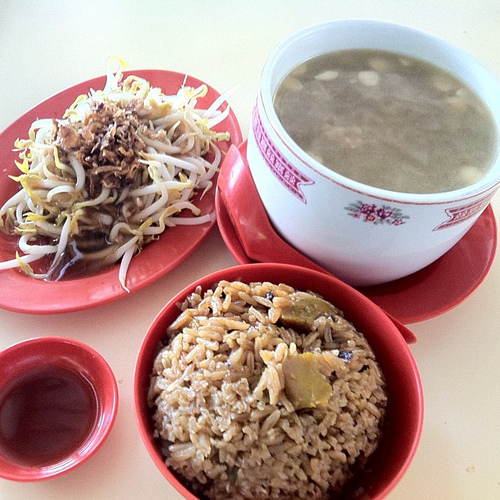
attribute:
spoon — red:
[218, 138, 430, 349]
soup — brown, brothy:
[279, 34, 499, 237]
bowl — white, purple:
[234, 10, 500, 291]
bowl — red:
[113, 248, 436, 497]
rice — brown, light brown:
[182, 295, 361, 472]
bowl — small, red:
[1, 323, 132, 473]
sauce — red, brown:
[15, 370, 75, 408]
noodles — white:
[11, 136, 71, 266]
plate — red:
[1, 48, 254, 302]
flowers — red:
[344, 190, 427, 235]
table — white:
[1, 10, 497, 497]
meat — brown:
[68, 95, 154, 175]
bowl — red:
[216, 87, 499, 343]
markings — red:
[249, 98, 499, 231]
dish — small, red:
[5, 320, 132, 484]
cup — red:
[1, 321, 137, 472]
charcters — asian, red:
[251, 97, 317, 206]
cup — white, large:
[244, 19, 496, 290]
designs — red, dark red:
[251, 117, 485, 271]